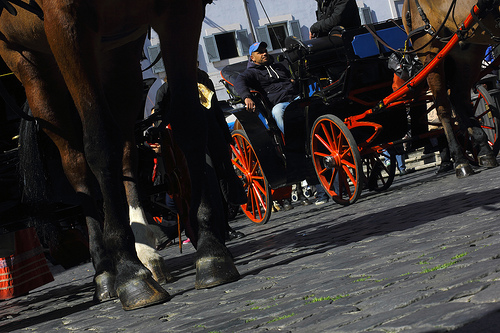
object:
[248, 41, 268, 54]
cap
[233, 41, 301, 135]
man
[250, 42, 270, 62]
head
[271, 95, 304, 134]
jeans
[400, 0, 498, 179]
horse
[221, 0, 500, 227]
carriage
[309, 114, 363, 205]
wheel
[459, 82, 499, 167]
wheel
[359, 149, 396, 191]
wheel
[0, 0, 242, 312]
horse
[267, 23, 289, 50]
windows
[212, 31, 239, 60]
window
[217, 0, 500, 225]
blue wagon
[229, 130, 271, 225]
red wheels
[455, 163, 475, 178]
hoof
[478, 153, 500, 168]
hoof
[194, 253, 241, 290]
hoof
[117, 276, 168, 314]
hoof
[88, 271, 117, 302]
hoof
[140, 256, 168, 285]
hoof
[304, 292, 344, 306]
grass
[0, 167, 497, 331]
brick pavement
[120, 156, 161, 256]
leg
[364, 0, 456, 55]
straps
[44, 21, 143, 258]
leg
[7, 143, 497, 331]
pavement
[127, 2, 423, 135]
building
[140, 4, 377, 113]
house